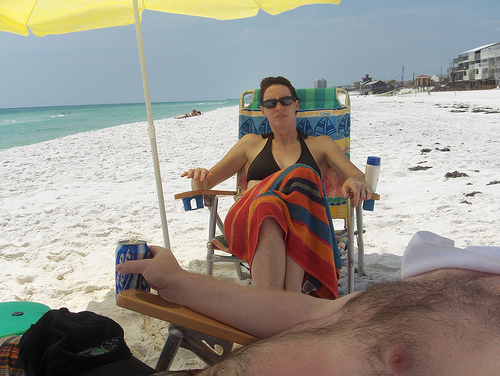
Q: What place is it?
A: It is a beach.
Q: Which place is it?
A: It is a beach.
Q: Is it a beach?
A: Yes, it is a beach.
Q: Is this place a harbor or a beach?
A: It is a beach.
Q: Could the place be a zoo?
A: No, it is a beach.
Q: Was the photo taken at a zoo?
A: No, the picture was taken in a beach.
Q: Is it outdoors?
A: Yes, it is outdoors.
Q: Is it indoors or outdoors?
A: It is outdoors.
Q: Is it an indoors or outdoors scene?
A: It is outdoors.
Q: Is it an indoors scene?
A: No, it is outdoors.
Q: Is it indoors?
A: No, it is outdoors.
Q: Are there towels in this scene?
A: Yes, there is a towel.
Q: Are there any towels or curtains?
A: Yes, there is a towel.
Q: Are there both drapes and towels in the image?
A: No, there is a towel but no drapes.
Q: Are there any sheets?
A: No, there are no sheets.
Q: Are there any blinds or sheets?
A: No, there are no sheets or blinds.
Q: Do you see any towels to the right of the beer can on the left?
A: Yes, there is a towel to the right of the beer can.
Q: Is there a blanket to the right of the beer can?
A: No, there is a towel to the right of the beer can.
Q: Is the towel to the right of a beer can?
A: Yes, the towel is to the right of a beer can.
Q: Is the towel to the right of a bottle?
A: No, the towel is to the right of a beer can.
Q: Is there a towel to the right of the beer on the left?
A: Yes, there is a towel to the right of the beer.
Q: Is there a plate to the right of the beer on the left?
A: No, there is a towel to the right of the beer.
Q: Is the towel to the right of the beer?
A: Yes, the towel is to the right of the beer.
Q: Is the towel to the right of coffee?
A: No, the towel is to the right of the beer.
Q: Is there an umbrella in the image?
A: Yes, there is an umbrella.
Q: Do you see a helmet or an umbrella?
A: Yes, there is an umbrella.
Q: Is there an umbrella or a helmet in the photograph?
A: Yes, there is an umbrella.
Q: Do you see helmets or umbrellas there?
A: Yes, there is an umbrella.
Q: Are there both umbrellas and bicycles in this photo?
A: No, there is an umbrella but no bikes.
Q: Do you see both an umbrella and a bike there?
A: No, there is an umbrella but no bikes.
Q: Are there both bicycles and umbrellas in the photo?
A: No, there is an umbrella but no bikes.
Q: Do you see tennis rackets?
A: No, there are no tennis rackets.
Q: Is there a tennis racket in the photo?
A: No, there are no rackets.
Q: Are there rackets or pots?
A: No, there are no rackets or pots.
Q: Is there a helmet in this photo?
A: No, there are no helmets.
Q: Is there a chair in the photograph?
A: Yes, there is a chair.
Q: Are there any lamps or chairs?
A: Yes, there is a chair.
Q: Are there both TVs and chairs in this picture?
A: No, there is a chair but no televisions.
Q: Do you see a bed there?
A: No, there are no beds.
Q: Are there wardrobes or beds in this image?
A: No, there are no beds or wardrobes.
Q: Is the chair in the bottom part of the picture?
A: Yes, the chair is in the bottom of the image.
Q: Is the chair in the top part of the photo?
A: No, the chair is in the bottom of the image.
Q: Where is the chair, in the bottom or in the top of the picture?
A: The chair is in the bottom of the image.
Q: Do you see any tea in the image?
A: No, there is no tea.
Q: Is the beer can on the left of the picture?
A: Yes, the beer can is on the left of the image.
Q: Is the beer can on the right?
A: No, the beer can is on the left of the image.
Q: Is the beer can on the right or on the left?
A: The beer can is on the left of the image.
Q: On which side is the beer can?
A: The beer can is on the left of the image.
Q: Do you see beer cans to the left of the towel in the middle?
A: Yes, there is a beer can to the left of the towel.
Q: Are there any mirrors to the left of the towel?
A: No, there is a beer can to the left of the towel.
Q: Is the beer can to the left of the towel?
A: Yes, the beer can is to the left of the towel.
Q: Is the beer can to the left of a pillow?
A: No, the beer can is to the left of the towel.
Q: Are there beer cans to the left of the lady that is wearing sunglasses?
A: Yes, there is a beer can to the left of the lady.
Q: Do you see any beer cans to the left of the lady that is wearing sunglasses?
A: Yes, there is a beer can to the left of the lady.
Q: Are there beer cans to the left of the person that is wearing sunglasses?
A: Yes, there is a beer can to the left of the lady.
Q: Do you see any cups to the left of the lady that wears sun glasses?
A: No, there is a beer can to the left of the lady.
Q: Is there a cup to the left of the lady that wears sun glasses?
A: No, there is a beer can to the left of the lady.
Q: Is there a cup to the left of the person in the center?
A: No, there is a beer can to the left of the lady.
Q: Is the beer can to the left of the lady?
A: Yes, the beer can is to the left of the lady.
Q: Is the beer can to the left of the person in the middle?
A: Yes, the beer can is to the left of the lady.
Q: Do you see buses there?
A: No, there are no buses.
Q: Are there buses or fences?
A: No, there are no buses or fences.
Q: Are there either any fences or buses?
A: No, there are no buses or fences.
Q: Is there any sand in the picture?
A: Yes, there is sand.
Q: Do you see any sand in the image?
A: Yes, there is sand.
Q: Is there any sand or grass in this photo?
A: Yes, there is sand.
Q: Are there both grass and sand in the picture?
A: No, there is sand but no grass.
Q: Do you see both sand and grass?
A: No, there is sand but no grass.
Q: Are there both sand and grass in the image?
A: No, there is sand but no grass.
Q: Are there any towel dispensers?
A: No, there are no towel dispensers.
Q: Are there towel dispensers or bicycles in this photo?
A: No, there are no towel dispensers or bicycles.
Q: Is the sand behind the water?
A: Yes, the sand is behind the water.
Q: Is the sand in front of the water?
A: No, the sand is behind the water.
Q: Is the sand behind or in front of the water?
A: The sand is behind the water.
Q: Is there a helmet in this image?
A: No, there are no helmets.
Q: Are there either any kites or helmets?
A: No, there are no helmets or kites.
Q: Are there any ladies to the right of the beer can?
A: Yes, there is a lady to the right of the beer can.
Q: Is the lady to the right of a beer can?
A: Yes, the lady is to the right of a beer can.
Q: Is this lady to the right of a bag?
A: No, the lady is to the right of a beer can.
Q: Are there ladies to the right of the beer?
A: Yes, there is a lady to the right of the beer.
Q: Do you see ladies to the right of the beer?
A: Yes, there is a lady to the right of the beer.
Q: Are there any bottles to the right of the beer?
A: No, there is a lady to the right of the beer.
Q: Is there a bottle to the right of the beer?
A: No, there is a lady to the right of the beer.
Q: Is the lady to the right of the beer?
A: Yes, the lady is to the right of the beer.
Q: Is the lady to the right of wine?
A: No, the lady is to the right of the beer.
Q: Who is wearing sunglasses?
A: The lady is wearing sunglasses.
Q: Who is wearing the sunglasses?
A: The lady is wearing sunglasses.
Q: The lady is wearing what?
A: The lady is wearing sunglasses.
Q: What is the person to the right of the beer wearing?
A: The lady is wearing sunglasses.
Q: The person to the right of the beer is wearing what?
A: The lady is wearing sunglasses.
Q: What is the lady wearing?
A: The lady is wearing sunglasses.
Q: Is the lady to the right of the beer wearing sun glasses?
A: Yes, the lady is wearing sun glasses.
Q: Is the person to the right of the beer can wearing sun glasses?
A: Yes, the lady is wearing sun glasses.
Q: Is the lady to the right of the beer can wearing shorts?
A: No, the lady is wearing sun glasses.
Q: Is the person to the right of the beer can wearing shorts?
A: No, the lady is wearing sun glasses.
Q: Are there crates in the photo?
A: No, there are no crates.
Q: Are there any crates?
A: No, there are no crates.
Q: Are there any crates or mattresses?
A: No, there are no crates or mattresses.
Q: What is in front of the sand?
A: The water is in front of the sand.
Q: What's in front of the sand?
A: The water is in front of the sand.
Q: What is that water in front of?
A: The water is in front of the sand.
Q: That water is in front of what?
A: The water is in front of the sand.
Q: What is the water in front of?
A: The water is in front of the sand.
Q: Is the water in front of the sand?
A: Yes, the water is in front of the sand.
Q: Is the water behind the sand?
A: No, the water is in front of the sand.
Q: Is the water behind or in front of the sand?
A: The water is in front of the sand.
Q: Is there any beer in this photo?
A: Yes, there is beer.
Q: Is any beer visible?
A: Yes, there is beer.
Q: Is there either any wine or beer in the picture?
A: Yes, there is beer.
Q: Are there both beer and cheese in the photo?
A: No, there is beer but no cheese.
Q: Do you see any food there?
A: No, there is no food.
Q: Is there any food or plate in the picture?
A: No, there are no food or plates.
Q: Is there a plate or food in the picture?
A: No, there are no food or plates.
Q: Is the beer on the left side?
A: Yes, the beer is on the left of the image.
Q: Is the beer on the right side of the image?
A: No, the beer is on the left of the image.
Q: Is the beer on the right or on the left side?
A: The beer is on the left of the image.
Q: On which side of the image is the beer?
A: The beer is on the left of the image.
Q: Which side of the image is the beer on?
A: The beer is on the left of the image.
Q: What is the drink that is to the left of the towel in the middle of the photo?
A: The drink is beer.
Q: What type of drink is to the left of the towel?
A: The drink is beer.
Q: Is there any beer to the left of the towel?
A: Yes, there is beer to the left of the towel.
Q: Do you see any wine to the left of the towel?
A: No, there is beer to the left of the towel.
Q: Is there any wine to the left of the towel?
A: No, there is beer to the left of the towel.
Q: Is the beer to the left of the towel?
A: Yes, the beer is to the left of the towel.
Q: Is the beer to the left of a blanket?
A: No, the beer is to the left of the towel.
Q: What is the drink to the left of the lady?
A: The drink is beer.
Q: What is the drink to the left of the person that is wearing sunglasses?
A: The drink is beer.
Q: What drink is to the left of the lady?
A: The drink is beer.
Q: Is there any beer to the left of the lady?
A: Yes, there is beer to the left of the lady.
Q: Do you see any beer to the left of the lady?
A: Yes, there is beer to the left of the lady.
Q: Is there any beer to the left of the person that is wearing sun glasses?
A: Yes, there is beer to the left of the lady.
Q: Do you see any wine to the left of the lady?
A: No, there is beer to the left of the lady.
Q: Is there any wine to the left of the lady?
A: No, there is beer to the left of the lady.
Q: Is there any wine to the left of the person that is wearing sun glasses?
A: No, there is beer to the left of the lady.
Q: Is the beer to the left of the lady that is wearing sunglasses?
A: Yes, the beer is to the left of the lady.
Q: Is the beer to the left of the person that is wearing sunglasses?
A: Yes, the beer is to the left of the lady.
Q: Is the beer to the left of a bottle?
A: No, the beer is to the left of the lady.